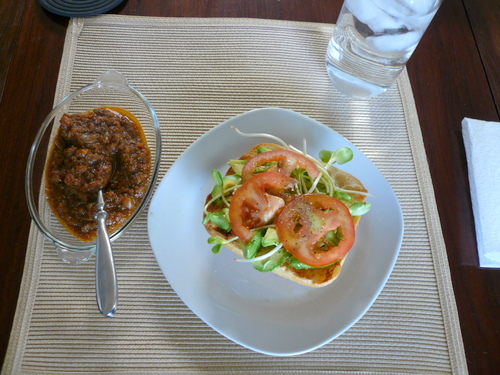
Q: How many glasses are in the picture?
A: One.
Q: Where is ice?
A: In a glass.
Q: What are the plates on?
A: A placemat.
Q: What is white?
A: A plate.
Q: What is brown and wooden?
A: The table.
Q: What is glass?
A: A bowl.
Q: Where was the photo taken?
A: At the kitchen table.